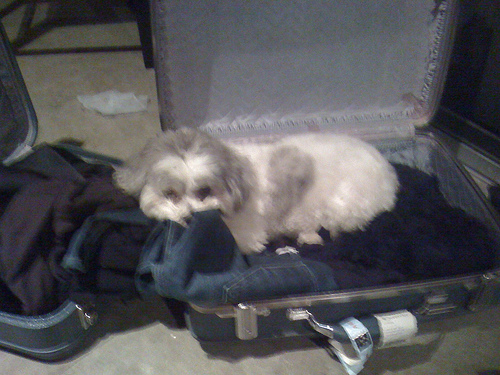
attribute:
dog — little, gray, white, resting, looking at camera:
[114, 128, 401, 253]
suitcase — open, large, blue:
[151, 0, 498, 344]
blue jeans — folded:
[134, 211, 337, 305]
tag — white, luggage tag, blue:
[330, 316, 372, 373]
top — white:
[148, 1, 458, 140]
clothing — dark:
[298, 160, 494, 289]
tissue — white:
[76, 87, 150, 115]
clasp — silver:
[76, 299, 101, 331]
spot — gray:
[263, 146, 315, 219]